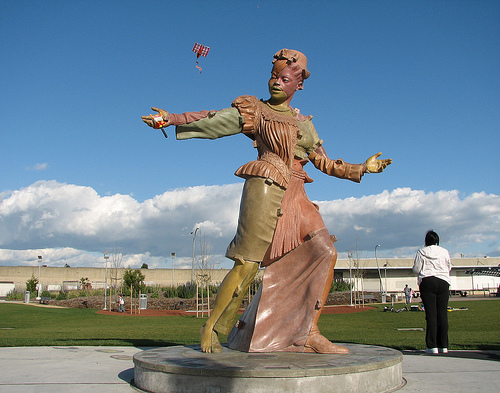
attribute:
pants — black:
[418, 276, 449, 349]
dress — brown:
[232, 95, 335, 358]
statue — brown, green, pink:
[141, 47, 394, 355]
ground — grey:
[1, 343, 497, 392]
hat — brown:
[271, 48, 310, 79]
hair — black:
[424, 230, 440, 244]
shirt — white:
[412, 246, 453, 285]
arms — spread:
[143, 106, 394, 182]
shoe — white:
[427, 348, 438, 353]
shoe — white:
[441, 349, 449, 353]